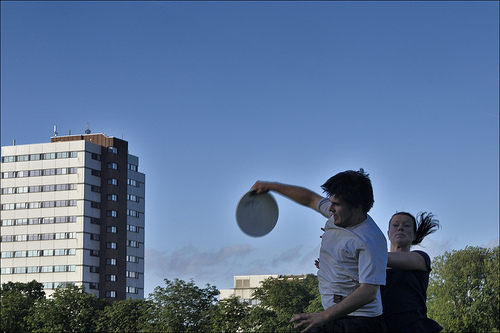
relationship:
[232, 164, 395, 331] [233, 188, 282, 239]
man holding frisbee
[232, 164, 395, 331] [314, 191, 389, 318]
man wearing tee shirt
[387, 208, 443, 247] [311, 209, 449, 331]
hair of woman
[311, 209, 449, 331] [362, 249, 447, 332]
woman wearing shirt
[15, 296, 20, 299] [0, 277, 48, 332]
leaf on tree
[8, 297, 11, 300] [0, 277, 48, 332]
leaf on tree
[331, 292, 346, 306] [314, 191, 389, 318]
logo on tee shirt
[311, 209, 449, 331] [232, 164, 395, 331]
woman grabbing man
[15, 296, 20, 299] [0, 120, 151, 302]
leaf front of building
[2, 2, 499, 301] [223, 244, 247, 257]
sky has cloud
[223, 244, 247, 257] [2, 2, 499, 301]
cloud on sky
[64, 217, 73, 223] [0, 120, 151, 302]
window on building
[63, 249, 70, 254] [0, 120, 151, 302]
window on building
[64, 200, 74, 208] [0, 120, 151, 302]
window on building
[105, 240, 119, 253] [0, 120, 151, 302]
window on building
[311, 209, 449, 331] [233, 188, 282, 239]
woman playing frisbee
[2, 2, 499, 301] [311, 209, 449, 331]
sky above woman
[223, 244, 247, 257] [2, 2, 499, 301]
cloud in sky